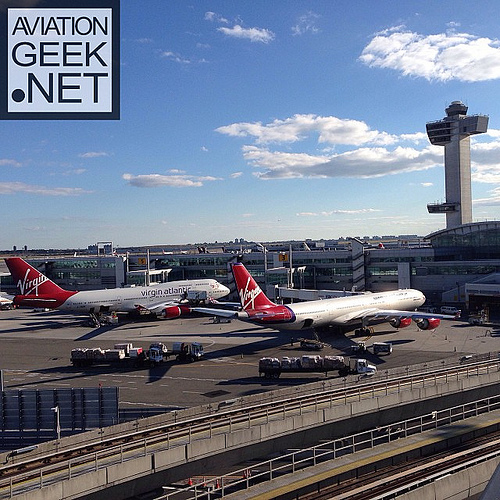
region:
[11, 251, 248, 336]
plane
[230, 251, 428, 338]
plane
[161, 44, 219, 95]
white clouds in blue sky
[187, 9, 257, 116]
white clouds in blue sky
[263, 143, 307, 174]
white clouds in blue sky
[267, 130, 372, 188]
white clouds in blue sky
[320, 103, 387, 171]
white clouds in blue sky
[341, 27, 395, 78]
white clouds in blue sky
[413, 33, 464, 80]
white clouds in blue sky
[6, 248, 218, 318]
red and white plane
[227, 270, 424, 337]
white and red plane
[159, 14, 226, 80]
white clouds in blue sky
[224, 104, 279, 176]
white clouds in blue sky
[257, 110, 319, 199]
white clouds in blue sky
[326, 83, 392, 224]
white clouds in blue sky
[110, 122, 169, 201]
white clouds in blue sky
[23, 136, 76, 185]
white clouds in blue sky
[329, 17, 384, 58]
white clouds in blue sky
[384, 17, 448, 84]
white clouds in blue sky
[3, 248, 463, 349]
Airplanes parked on tarmac in front of passenger terminal.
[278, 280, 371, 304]
Passenger load and unload ramp.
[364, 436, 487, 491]
Trolley car track at airport.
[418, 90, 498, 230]
Air traffic control tower.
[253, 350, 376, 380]
Truck loaded with packages.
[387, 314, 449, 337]
Two jet engines mounted under plane's wing.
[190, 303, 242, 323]
Rear horizontal stabilizer on plane.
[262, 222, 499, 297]
Passenger terminal at airport.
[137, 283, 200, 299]
Name of airline on side of plane.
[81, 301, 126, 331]
Luggage being loaded in cargo bay.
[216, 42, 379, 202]
The sky is blue and cloudy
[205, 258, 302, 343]
The wing of the plane is yellow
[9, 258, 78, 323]
The plane says virgin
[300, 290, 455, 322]
The plane is silver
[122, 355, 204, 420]
The runway is dark with lines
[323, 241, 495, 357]
The building is in the back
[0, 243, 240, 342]
The plane is parked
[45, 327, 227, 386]
The luggage is on the tarmack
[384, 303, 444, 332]
The wing has red on it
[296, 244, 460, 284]
The building has many windows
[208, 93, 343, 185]
white clouds in sky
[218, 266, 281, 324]
tail of the plane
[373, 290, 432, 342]
wing of the plane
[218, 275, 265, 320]
word on tail of plane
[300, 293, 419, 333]
side of the plane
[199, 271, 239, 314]
nose of the plane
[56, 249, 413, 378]
two planes next to each other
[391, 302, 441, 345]
engines on side of plane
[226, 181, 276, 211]
blue sky above the land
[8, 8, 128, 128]
words in top left corner